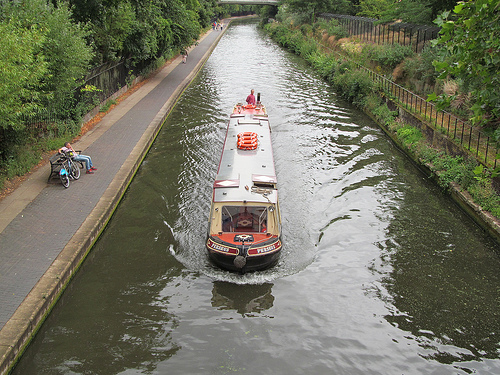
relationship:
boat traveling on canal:
[200, 93, 290, 276] [10, 17, 497, 373]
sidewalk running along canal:
[54, 52, 185, 145] [10, 17, 497, 373]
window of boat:
[220, 202, 271, 232] [181, 83, 289, 304]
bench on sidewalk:
[44, 143, 84, 188] [161, 26, 201, 127]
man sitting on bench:
[58, 142, 97, 174] [43, 137, 95, 189]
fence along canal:
[289, 7, 499, 211] [10, 17, 497, 373]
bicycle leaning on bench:
[53, 153, 81, 188] [46, 149, 83, 183]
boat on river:
[203, 93, 284, 274] [202, 86, 285, 275]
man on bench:
[55, 140, 98, 172] [46, 149, 83, 183]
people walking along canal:
[207, 14, 226, 31] [10, 17, 497, 373]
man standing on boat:
[243, 87, 259, 106] [163, 61, 322, 311]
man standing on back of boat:
[246, 88, 256, 106] [203, 93, 284, 274]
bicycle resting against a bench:
[55, 150, 80, 189] [46, 150, 81, 181]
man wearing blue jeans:
[58, 142, 97, 174] [73, 154, 93, 169]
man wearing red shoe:
[58, 142, 97, 174] [85, 169, 94, 174]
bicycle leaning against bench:
[55, 150, 80, 189] [49, 148, 83, 193]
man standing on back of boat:
[246, 88, 256, 106] [204, 75, 280, 276]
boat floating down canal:
[203, 93, 284, 274] [10, 17, 497, 373]